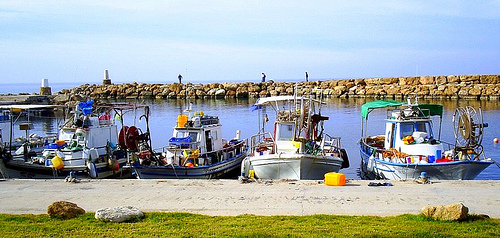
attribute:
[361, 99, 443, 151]
canopy — green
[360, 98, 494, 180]
boat — blue, white, docked, parked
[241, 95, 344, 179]
boat — white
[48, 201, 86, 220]
rock — brown, white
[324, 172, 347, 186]
jug — yellow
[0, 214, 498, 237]
grass — green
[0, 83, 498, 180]
water — blue, calm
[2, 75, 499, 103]
rock wall — brown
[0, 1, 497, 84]
sky — blue, bright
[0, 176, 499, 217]
sand — gray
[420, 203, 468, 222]
rock — gray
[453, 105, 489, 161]
fan — large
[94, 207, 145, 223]
rock — white